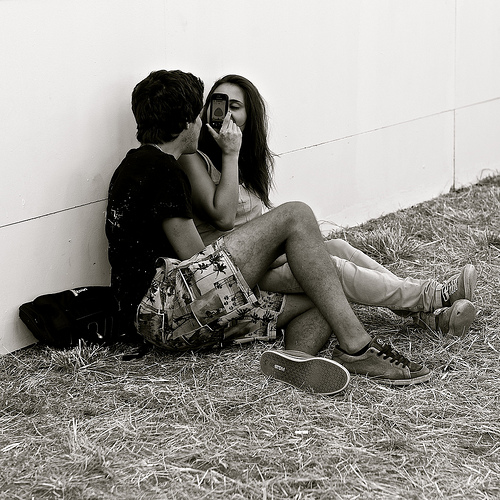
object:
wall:
[2, 2, 499, 265]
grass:
[0, 175, 499, 499]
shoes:
[258, 334, 433, 396]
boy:
[104, 58, 210, 351]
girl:
[198, 72, 478, 341]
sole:
[269, 362, 292, 379]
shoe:
[260, 344, 351, 396]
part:
[0, 224, 25, 350]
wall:
[31, 94, 103, 174]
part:
[182, 275, 273, 360]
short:
[142, 252, 286, 360]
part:
[328, 293, 347, 326]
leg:
[272, 242, 385, 344]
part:
[10, 308, 62, 379]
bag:
[20, 275, 118, 353]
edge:
[227, 272, 265, 324]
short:
[210, 302, 240, 360]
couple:
[104, 64, 478, 396]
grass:
[36, 372, 251, 484]